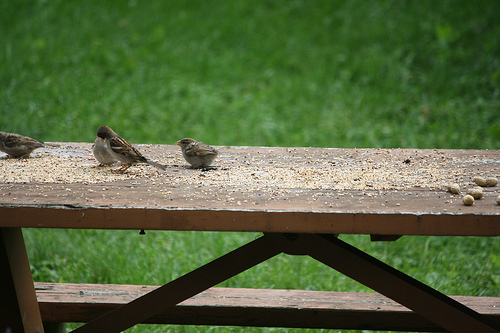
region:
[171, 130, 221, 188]
a sparrow bird on picnic table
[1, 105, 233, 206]
a group of birds on a picnic table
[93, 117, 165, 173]
a finch bird standing on table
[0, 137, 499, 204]
a picnic table with bird seed spread on it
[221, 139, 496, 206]
bird seed on table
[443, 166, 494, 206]
a group of nuts on picnic table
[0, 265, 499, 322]
a bench on picnic table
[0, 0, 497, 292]
a grassy area around park bench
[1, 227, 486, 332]
a beam holding up picnic table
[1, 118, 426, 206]
birds eating seed on a old picnic table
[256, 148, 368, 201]
Birdseed for the birds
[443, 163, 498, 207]
nuts for the birds to eat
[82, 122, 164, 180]
a pair of beautiful birds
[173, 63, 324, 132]
Green grass behind the picnic table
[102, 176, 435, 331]
picnic table in the back yard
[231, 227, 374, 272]
supports for the picnic table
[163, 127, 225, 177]
single bird eating the seed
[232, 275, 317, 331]
bench to the brown picnic table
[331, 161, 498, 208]
combination of birdseed and nuts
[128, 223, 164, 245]
the nail holding the table together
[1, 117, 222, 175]
birds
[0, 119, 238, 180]
four birds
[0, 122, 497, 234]
four birds on a wooden railing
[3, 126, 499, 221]
the birds are on a wooden fence rail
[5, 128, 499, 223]
birdseed is on the railing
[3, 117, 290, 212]
the birds stand in birdseed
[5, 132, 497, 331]
a wooden fence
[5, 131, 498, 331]
the wooden fence is next to a field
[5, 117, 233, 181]
the birds are gathered on a railing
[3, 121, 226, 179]
the birds are small and brown in color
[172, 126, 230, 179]
a small round bird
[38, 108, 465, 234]
birdseed on a plank of wood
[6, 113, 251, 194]
small birds sitting on wood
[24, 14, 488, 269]
very green patch of lawn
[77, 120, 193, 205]
light and dark brown bird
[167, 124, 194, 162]
small yellow bird beak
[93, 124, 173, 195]
small brown bird standing up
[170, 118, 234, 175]
small bird sitting down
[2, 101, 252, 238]
group of birds eating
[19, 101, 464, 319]
planks of wood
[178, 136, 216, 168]
brown bird sitting on wooden bench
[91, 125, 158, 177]
brown bird sitting on wooden bench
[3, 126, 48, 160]
brown bird sitting on wooden bench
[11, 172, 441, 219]
brown and tan wooden bench seat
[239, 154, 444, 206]
brown and tan wooden bench seat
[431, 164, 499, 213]
nuts on wooden seat of bench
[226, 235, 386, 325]
brown wooden support of bench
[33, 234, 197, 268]
short green grass near bench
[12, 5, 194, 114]
short green grass near bench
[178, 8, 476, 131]
short green grass near bench